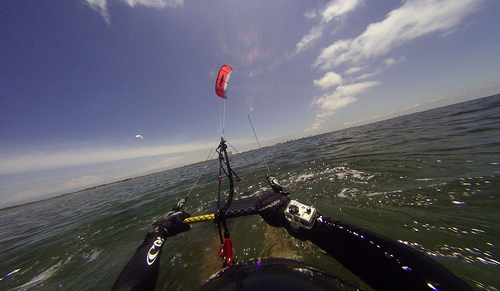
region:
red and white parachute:
[201, 55, 234, 95]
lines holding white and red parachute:
[165, 86, 290, 187]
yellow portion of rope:
[180, 211, 210, 221]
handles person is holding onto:
[146, 192, 289, 222]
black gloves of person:
[152, 205, 287, 230]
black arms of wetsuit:
[111, 231, 449, 289]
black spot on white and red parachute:
[212, 71, 227, 84]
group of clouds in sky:
[294, 39, 398, 126]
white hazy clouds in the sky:
[5, 130, 296, 187]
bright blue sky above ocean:
[10, 10, 490, 187]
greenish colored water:
[3, 94, 496, 289]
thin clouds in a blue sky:
[2, 0, 499, 212]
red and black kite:
[213, 62, 238, 99]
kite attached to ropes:
[171, 61, 287, 212]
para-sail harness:
[106, 192, 472, 289]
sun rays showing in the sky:
[190, 1, 277, 79]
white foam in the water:
[5, 160, 499, 286]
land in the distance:
[1, 173, 134, 213]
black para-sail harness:
[110, 187, 472, 289]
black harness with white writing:
[116, 189, 475, 285]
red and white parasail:
[211, 61, 234, 101]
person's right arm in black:
[249, 188, 484, 289]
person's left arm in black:
[106, 200, 207, 289]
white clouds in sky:
[266, 0, 481, 136]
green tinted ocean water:
[3, 85, 498, 289]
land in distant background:
[0, 168, 139, 210]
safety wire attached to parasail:
[227, 80, 289, 204]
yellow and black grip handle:
[150, 188, 291, 229]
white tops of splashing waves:
[276, 158, 393, 206]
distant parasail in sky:
[122, 129, 149, 146]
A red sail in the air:
[208, 60, 248, 128]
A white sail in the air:
[130, 131, 150, 152]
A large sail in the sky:
[204, 55, 244, 105]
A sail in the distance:
[126, 128, 149, 147]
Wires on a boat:
[242, 113, 277, 167]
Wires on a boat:
[191, 155, 209, 187]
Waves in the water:
[313, 161, 369, 198]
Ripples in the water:
[31, 254, 91, 279]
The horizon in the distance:
[320, 91, 499, 123]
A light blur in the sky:
[221, 27, 278, 67]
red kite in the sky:
[212, 58, 239, 105]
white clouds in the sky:
[296, 2, 466, 124]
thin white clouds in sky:
[314, 5, 474, 129]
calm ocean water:
[47, 191, 159, 238]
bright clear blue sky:
[7, 12, 169, 136]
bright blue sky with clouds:
[59, 4, 499, 103]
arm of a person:
[110, 205, 182, 289]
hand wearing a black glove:
[150, 209, 201, 241]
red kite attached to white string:
[200, 63, 245, 152]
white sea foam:
[302, 158, 380, 201]